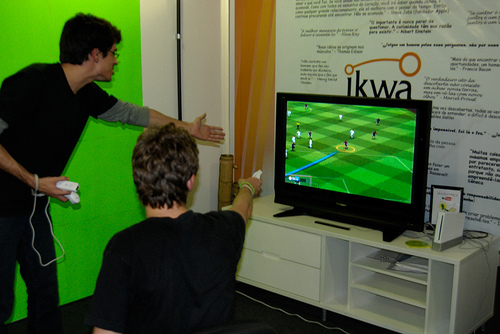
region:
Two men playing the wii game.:
[38, 35, 253, 319]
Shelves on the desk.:
[333, 226, 440, 330]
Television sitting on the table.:
[248, 85, 443, 240]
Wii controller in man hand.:
[26, 150, 79, 232]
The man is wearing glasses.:
[103, 40, 141, 57]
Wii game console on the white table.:
[436, 200, 474, 252]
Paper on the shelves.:
[381, 253, 429, 282]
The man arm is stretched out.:
[110, 88, 236, 155]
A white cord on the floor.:
[238, 285, 328, 332]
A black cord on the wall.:
[158, 8, 205, 123]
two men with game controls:
[5, 10, 258, 323]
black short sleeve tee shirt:
[92, 203, 247, 332]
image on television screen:
[282, 98, 417, 205]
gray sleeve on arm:
[96, 94, 223, 144]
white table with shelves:
[220, 193, 496, 332]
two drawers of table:
[232, 211, 321, 303]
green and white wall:
[5, 1, 224, 318]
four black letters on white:
[345, 71, 413, 100]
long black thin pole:
[175, 1, 182, 117]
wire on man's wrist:
[25, 173, 65, 265]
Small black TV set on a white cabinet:
[278, 87, 431, 244]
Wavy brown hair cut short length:
[131, 113, 201, 222]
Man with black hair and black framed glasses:
[58, 8, 125, 91]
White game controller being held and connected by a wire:
[26, 162, 86, 217]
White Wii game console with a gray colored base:
[425, 207, 475, 252]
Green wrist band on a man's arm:
[236, 173, 255, 197]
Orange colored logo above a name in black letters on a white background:
[341, 46, 429, 91]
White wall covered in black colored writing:
[286, 2, 496, 98]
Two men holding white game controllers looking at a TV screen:
[18, 25, 428, 320]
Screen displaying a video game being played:
[286, 97, 425, 203]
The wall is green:
[2, 2, 57, 84]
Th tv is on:
[273, 86, 444, 228]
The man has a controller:
[13, 158, 113, 270]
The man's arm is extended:
[43, 16, 263, 154]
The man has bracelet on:
[227, 167, 266, 214]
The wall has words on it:
[306, 30, 497, 146]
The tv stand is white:
[286, 225, 456, 332]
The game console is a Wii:
[420, 202, 482, 260]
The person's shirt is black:
[107, 212, 271, 329]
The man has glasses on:
[81, 37, 130, 69]